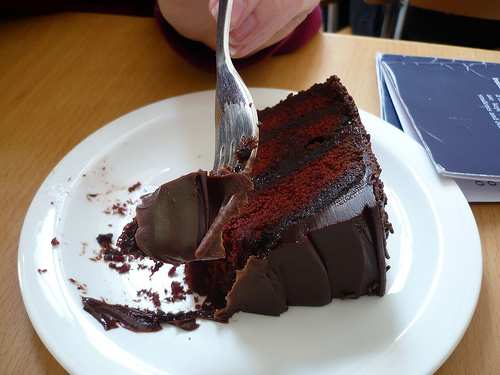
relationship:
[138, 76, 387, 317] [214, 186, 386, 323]
cake with chocolate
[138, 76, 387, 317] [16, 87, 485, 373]
cake on plate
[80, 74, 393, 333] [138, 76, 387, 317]
frosting on cake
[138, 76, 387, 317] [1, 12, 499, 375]
cake on table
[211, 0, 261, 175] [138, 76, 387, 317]
fork digging into cake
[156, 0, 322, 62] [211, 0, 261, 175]
hand holding fork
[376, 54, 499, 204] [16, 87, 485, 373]
book next to plate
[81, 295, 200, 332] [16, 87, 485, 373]
smudge on plate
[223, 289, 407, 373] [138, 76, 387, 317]
shadow by cake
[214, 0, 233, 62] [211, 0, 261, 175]
handle of fork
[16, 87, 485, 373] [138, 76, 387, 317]
plate holding cake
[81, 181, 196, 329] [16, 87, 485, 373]
frosting on plate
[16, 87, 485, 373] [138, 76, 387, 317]
plate of cake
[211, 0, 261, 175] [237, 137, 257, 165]
fork with cake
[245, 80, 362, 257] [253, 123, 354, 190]
lines of frosting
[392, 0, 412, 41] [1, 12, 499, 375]
pole behind table